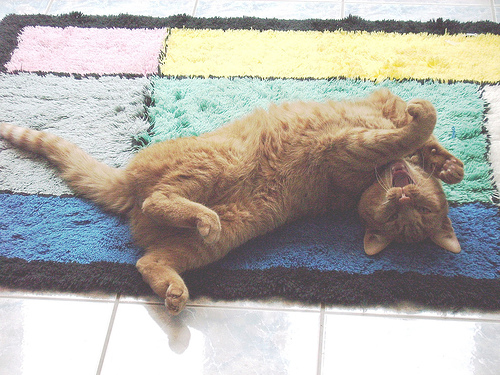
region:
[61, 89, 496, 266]
This is picture of a cat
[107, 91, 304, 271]
The cat is on the floor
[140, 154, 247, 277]
The cat is laying down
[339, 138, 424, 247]
The tongue is pink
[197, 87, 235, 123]
The rug is plush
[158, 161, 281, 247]
The cat is light brown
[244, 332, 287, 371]
This is a picture of tile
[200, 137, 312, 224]
The cat is stretching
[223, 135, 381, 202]
The cat is striped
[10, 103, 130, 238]
This is the tail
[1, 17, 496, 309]
multi clored rectangle rug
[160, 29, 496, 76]
yellow shag of rug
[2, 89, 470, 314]
cat on shag rug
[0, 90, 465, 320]
cat with twisted body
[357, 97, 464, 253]
cat paw in the air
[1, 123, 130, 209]
stripes on cat tail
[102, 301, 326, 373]
sqaure tile of floor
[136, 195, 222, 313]
back paws of cat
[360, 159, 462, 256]
upside down cat head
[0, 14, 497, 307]
rug with black trim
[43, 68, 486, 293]
cat on the ground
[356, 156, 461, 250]
head of the cat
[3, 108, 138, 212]
tail of the cat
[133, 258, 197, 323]
foot of the cat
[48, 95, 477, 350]
cat laying on back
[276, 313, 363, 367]
line on the tile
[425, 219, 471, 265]
ear of the cat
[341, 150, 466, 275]
cat with mouth open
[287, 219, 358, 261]
blue rug under cat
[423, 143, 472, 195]
paw of the cat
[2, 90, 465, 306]
cat laying on rug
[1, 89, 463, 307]
orange and white cat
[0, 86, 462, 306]
tabby cat on floor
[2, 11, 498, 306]
bath mat on floor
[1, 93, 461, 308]
orange tabby cat on rug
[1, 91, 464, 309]
tabby cat yawning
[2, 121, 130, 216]
white and orange tail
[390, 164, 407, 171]
white teeth on cat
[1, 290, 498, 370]
white ceramic floor tiles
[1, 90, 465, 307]
orange cat on back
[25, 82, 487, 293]
th cat is lying on its back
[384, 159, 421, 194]
the cats mouth is open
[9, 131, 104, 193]
the cat has a tail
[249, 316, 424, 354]
the floor is tile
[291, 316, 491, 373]
the floor is shiney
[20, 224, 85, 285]
the rug is blue and black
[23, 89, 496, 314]
the cat is orange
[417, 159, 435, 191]
the cat has whiskers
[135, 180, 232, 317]
the cat has backpaws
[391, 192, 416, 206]
the cat has a nose